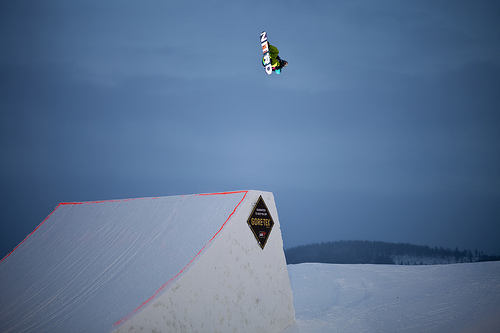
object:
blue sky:
[0, 0, 500, 258]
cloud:
[0, 0, 500, 258]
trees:
[293, 224, 499, 267]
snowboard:
[259, 31, 272, 76]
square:
[0, 190, 249, 333]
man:
[262, 45, 289, 75]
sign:
[247, 195, 275, 250]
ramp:
[2, 188, 295, 330]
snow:
[286, 262, 497, 331]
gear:
[262, 45, 288, 75]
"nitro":
[259, 31, 272, 75]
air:
[0, 0, 500, 333]